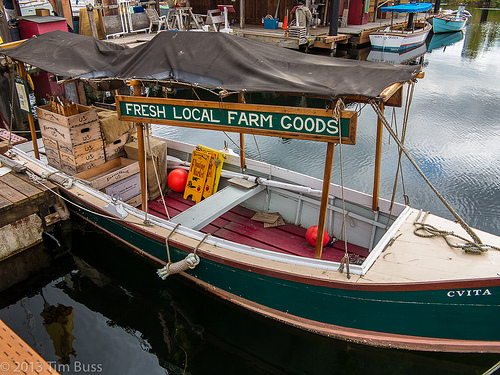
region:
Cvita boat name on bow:
[440, 286, 494, 301]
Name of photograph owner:
[1, 355, 106, 370]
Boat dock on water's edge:
[7, 28, 497, 358]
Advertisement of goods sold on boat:
[108, 94, 362, 144]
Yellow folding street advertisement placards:
[179, 145, 221, 203]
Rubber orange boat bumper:
[300, 224, 335, 250]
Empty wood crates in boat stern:
[35, 93, 166, 211]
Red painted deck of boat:
[137, 183, 378, 273]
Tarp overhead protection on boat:
[12, 25, 419, 112]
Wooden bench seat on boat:
[157, 179, 260, 236]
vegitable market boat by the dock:
[2, 27, 499, 353]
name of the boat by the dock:
[443, 287, 493, 300]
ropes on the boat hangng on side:
[156, 251, 200, 278]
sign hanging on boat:
[113, 91, 358, 147]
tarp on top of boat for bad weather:
[2, 28, 422, 98]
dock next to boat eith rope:
[0, 161, 68, 260]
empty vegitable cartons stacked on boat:
[33, 98, 113, 174]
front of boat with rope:
[366, 206, 498, 294]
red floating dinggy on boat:
[164, 167, 189, 192]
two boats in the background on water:
[368, 3, 471, 50]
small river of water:
[438, 61, 498, 183]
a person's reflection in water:
[38, 296, 86, 366]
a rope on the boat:
[379, 108, 478, 245]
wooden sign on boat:
[119, 98, 342, 138]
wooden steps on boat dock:
[4, 172, 44, 198]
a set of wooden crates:
[29, 112, 105, 169]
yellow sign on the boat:
[182, 145, 219, 199]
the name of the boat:
[442, 277, 498, 308]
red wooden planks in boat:
[226, 218, 308, 253]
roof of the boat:
[138, 58, 401, 101]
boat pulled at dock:
[8, 72, 498, 370]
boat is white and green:
[19, 28, 494, 370]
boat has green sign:
[109, 87, 366, 168]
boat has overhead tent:
[0, 15, 424, 163]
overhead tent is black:
[6, 27, 441, 155]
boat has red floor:
[121, 142, 373, 291]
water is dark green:
[41, 248, 215, 368]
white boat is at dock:
[364, 4, 453, 66]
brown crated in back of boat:
[31, 87, 159, 218]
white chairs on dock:
[126, 5, 220, 35]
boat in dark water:
[3, 30, 498, 351]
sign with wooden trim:
[114, 95, 355, 145]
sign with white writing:
[115, 95, 355, 143]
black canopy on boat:
[3, 28, 422, 101]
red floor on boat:
[137, 184, 370, 267]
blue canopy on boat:
[376, 4, 435, 13]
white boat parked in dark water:
[369, 22, 435, 54]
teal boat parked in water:
[434, 9, 470, 37]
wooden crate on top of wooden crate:
[34, 116, 101, 146]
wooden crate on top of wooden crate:
[38, 135, 104, 157]